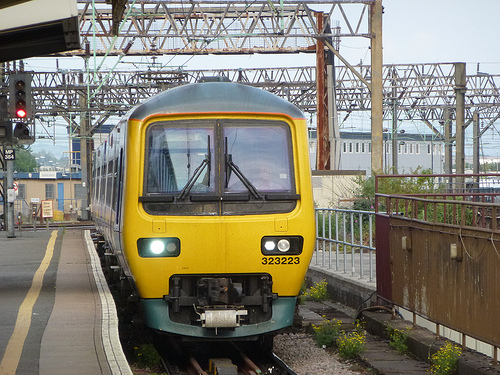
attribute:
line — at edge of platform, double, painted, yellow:
[17, 245, 62, 324]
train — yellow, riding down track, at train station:
[82, 80, 313, 343]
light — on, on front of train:
[122, 223, 193, 261]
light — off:
[259, 220, 306, 264]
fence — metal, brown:
[375, 174, 489, 325]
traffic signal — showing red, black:
[5, 66, 39, 134]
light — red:
[12, 106, 39, 122]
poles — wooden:
[370, 14, 484, 174]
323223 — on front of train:
[264, 258, 305, 266]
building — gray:
[315, 129, 450, 173]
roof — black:
[308, 126, 464, 146]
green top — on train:
[138, 75, 295, 120]